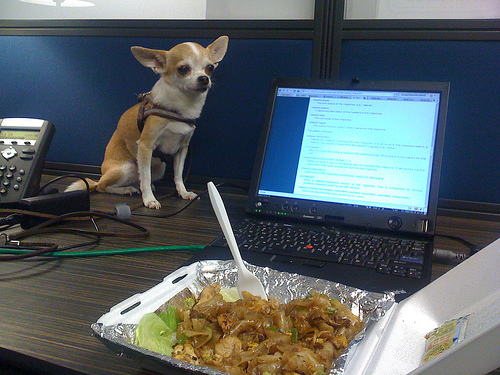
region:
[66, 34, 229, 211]
A brown and white chihuahua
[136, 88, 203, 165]
A harness on a dog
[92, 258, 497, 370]
A container of take out food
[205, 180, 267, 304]
A white plastic fork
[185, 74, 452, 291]
A black laptop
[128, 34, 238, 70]
Two dog ears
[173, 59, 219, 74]
A dog's brown eyes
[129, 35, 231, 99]
The face of a dog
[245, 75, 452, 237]
The screen of a laptop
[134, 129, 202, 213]
A dog's front legs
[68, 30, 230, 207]
a dog is on the desk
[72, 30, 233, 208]
a small dog is on the desk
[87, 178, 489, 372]
food in a Styrofoam container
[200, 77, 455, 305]
a laptop computer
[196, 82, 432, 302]
the computer is powered on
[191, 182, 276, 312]
a plastic fork is in the food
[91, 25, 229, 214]
the dog is wearing a harness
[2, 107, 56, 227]
a telephone is on the table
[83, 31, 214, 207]
the dog is tan and white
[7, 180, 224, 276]
wires are on the table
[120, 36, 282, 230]
a dog sitting on the table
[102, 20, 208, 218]
a dog sitting on the table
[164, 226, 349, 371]
food in a Styrofoam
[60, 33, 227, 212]
Chihuaha standing on wooden table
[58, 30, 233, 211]
Chihuaha standing near laptop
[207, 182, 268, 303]
White fork in tray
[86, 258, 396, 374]
Foil covering white tray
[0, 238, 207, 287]
Green cable plugged into laptop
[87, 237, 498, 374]
White tray in front of laptop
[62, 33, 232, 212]
Chihuaha wearing leash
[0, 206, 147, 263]
Brown cable on green cable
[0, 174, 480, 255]
Black cable running behind laptop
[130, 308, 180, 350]
Lettuce in white tray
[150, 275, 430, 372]
the food on the table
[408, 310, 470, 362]
the packets of condiments beside the food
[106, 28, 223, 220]
the dog on the table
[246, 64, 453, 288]
the laptop on the table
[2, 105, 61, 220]
the phone on the table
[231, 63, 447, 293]
the laptop is on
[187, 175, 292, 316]
the fork in the food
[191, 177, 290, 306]
the fork is plastic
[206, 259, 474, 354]
the foil under the food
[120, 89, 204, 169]
the harness on the dog